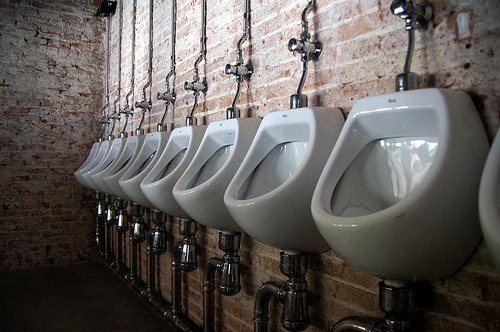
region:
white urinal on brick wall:
[70, 136, 96, 184]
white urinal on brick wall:
[87, 139, 95, 185]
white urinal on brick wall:
[110, 130, 118, 186]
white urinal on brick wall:
[118, 134, 138, 184]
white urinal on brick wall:
[134, 127, 162, 187]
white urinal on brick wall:
[167, 125, 187, 190]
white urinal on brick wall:
[207, 112, 242, 206]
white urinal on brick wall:
[256, 118, 307, 253]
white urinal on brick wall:
[330, 96, 452, 265]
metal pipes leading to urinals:
[95, 33, 402, 90]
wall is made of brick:
[2, 3, 497, 320]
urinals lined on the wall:
[69, 86, 498, 283]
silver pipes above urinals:
[91, 2, 471, 142]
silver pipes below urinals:
[83, 188, 426, 328]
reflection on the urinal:
[370, 131, 440, 203]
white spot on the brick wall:
[451, 7, 476, 52]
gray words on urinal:
[276, 111, 296, 121]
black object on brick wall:
[88, 0, 121, 20]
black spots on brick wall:
[456, 42, 476, 73]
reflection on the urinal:
[270, 139, 307, 184]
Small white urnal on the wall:
[460, 91, 497, 269]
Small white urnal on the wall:
[333, 95, 445, 264]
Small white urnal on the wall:
[237, 102, 299, 254]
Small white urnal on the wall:
[186, 115, 228, 241]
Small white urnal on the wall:
[153, 120, 183, 205]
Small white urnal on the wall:
[137, 122, 149, 194]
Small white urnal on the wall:
[100, 131, 145, 193]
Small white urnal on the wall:
[73, 134, 128, 192]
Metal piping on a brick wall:
[72, 70, 361, 118]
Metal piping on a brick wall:
[64, 191, 192, 301]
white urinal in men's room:
[301, 88, 481, 282]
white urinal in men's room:
[226, 103, 334, 257]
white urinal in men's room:
[167, 111, 257, 236]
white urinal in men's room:
[135, 122, 197, 216]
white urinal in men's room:
[113, 128, 167, 215]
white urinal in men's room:
[96, 128, 150, 209]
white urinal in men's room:
[86, 136, 131, 194]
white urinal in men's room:
[81, 141, 111, 182]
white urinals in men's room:
[73, 86, 498, 291]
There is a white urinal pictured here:
[330, 152, 367, 257]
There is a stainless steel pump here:
[261, 278, 275, 325]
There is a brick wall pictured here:
[28, 125, 72, 265]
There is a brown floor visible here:
[58, 285, 70, 325]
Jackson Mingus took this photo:
[30, 84, 82, 212]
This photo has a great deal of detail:
[38, 96, 115, 296]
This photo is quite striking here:
[45, 88, 128, 323]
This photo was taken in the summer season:
[28, 91, 123, 323]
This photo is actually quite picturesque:
[39, 82, 122, 319]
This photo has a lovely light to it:
[52, 86, 134, 307]